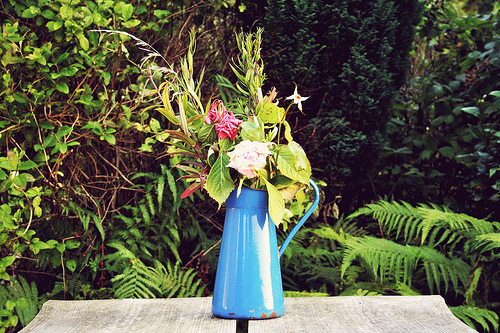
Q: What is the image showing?
A: It is showing a garden.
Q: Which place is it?
A: It is a garden.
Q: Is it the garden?
A: Yes, it is the garden.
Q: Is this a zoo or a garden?
A: It is a garden.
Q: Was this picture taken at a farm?
A: No, the picture was taken in a garden.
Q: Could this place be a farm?
A: No, it is a garden.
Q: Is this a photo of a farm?
A: No, the picture is showing a garden.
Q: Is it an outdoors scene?
A: Yes, it is outdoors.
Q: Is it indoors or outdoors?
A: It is outdoors.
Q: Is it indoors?
A: No, it is outdoors.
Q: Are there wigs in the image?
A: No, there are no wigs.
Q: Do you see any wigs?
A: No, there are no wigs.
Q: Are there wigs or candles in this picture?
A: No, there are no wigs or candles.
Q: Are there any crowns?
A: No, there are no crowns.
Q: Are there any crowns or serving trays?
A: No, there are no crowns or serving trays.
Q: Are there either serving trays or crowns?
A: No, there are no crowns or serving trays.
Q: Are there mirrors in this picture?
A: No, there are no mirrors.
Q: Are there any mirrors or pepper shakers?
A: No, there are no mirrors or pepper shakers.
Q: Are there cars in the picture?
A: No, there are no cars.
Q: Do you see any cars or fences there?
A: No, there are no cars or fences.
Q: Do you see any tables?
A: Yes, there is a table.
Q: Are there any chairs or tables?
A: Yes, there is a table.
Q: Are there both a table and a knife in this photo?
A: No, there is a table but no knives.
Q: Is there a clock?
A: No, there are no clocks.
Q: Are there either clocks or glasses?
A: No, there are no clocks or glasses.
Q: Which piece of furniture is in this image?
A: The piece of furniture is a table.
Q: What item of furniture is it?
A: The piece of furniture is a table.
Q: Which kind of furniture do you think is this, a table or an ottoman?
A: That is a table.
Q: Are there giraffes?
A: No, there are no giraffes.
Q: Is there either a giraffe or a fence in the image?
A: No, there are no giraffes or fences.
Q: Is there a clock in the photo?
A: No, there are no clocks.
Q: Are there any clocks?
A: No, there are no clocks.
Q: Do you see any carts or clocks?
A: No, there are no clocks or carts.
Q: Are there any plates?
A: No, there are no plates.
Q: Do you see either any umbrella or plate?
A: No, there are no plates or umbrellas.